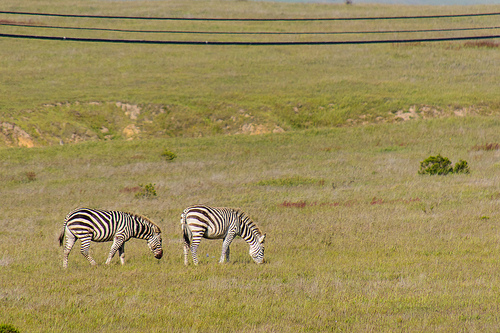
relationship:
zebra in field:
[165, 199, 276, 272] [319, 224, 391, 263]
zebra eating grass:
[165, 199, 276, 272] [297, 157, 335, 179]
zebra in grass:
[165, 199, 276, 272] [297, 157, 335, 179]